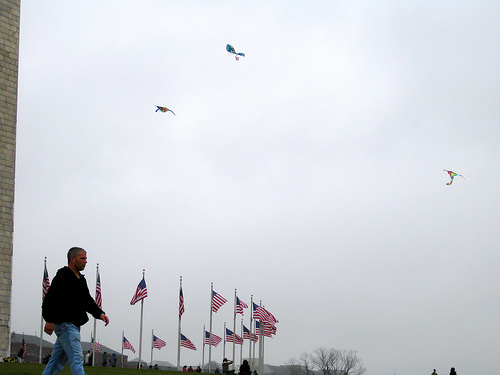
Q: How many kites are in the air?
A: 3.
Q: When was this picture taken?
A: Daytime.